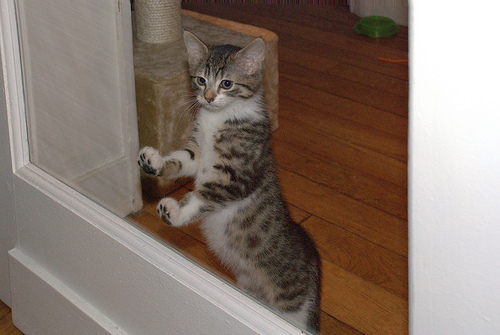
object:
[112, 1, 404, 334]
floor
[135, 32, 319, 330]
cat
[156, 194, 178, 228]
left paw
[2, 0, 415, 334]
door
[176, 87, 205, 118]
whiskers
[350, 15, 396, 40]
bowl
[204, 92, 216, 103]
nose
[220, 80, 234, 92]
left eye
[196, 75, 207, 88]
right eye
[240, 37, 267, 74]
left ear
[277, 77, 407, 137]
slat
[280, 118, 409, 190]
slat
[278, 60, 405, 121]
slat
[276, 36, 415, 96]
slat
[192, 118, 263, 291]
underbelly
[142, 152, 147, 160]
pad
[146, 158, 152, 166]
pad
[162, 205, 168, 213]
pad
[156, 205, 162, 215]
pad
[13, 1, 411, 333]
glass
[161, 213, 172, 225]
pad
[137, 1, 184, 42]
scratching pad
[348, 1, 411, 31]
wall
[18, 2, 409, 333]
room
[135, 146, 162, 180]
right paw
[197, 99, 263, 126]
neck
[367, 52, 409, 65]
object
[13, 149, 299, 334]
base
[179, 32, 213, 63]
right ear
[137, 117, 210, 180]
front leg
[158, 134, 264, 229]
front leg